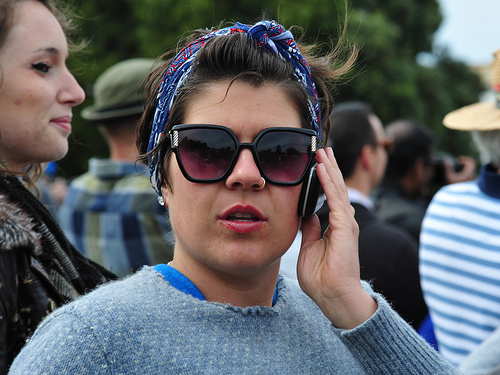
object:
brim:
[440, 103, 497, 131]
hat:
[444, 51, 499, 132]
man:
[414, 52, 499, 371]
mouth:
[213, 200, 275, 234]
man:
[55, 56, 172, 280]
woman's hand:
[296, 144, 362, 304]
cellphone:
[295, 164, 325, 218]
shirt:
[414, 163, 499, 366]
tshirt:
[152, 263, 210, 304]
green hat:
[78, 55, 167, 124]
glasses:
[158, 123, 318, 187]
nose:
[224, 150, 266, 190]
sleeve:
[338, 280, 463, 374]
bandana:
[144, 21, 329, 196]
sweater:
[8, 265, 479, 375]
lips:
[214, 220, 269, 234]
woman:
[0, 0, 124, 374]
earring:
[156, 195, 166, 207]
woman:
[6, 20, 465, 374]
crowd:
[0, 0, 498, 374]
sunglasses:
[150, 123, 317, 187]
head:
[140, 22, 334, 286]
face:
[164, 68, 302, 275]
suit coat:
[312, 203, 430, 337]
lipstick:
[212, 220, 264, 232]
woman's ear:
[151, 166, 172, 206]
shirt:
[58, 158, 175, 278]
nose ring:
[256, 177, 266, 190]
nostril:
[250, 171, 264, 190]